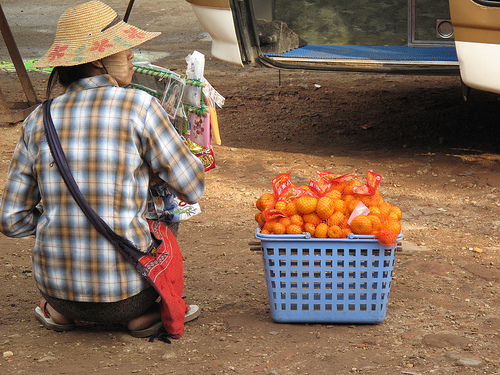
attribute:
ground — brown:
[2, 40, 499, 374]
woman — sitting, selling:
[7, 3, 204, 332]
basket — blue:
[256, 223, 402, 326]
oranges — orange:
[256, 175, 402, 240]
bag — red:
[141, 219, 186, 336]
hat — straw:
[36, 1, 161, 66]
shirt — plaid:
[5, 76, 202, 302]